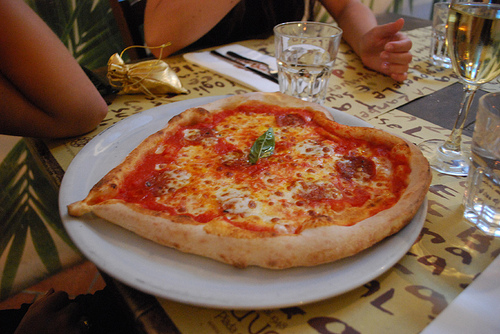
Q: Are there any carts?
A: No, there are no carts.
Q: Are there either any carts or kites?
A: No, there are no carts or kites.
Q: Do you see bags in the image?
A: Yes, there is a bag.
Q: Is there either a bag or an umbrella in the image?
A: Yes, there is a bag.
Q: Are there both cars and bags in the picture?
A: No, there is a bag but no cars.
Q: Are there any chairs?
A: No, there are no chairs.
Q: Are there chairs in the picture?
A: No, there are no chairs.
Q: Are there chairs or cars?
A: No, there are no chairs or cars.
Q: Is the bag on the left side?
A: Yes, the bag is on the left of the image.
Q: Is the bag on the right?
A: No, the bag is on the left of the image.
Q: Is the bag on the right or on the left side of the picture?
A: The bag is on the left of the image.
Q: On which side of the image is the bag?
A: The bag is on the left of the image.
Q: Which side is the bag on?
A: The bag is on the left of the image.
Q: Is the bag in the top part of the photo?
A: Yes, the bag is in the top of the image.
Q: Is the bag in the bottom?
A: No, the bag is in the top of the image.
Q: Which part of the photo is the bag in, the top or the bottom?
A: The bag is in the top of the image.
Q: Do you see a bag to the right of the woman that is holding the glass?
A: Yes, there is a bag to the right of the woman.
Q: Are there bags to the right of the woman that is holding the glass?
A: Yes, there is a bag to the right of the woman.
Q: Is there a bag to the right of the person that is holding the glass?
A: Yes, there is a bag to the right of the woman.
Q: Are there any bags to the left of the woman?
A: No, the bag is to the right of the woman.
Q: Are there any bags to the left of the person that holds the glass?
A: No, the bag is to the right of the woman.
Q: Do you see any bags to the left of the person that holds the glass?
A: No, the bag is to the right of the woman.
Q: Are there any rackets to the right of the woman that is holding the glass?
A: No, there is a bag to the right of the woman.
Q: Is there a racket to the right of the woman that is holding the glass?
A: No, there is a bag to the right of the woman.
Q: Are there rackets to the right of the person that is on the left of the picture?
A: No, there is a bag to the right of the woman.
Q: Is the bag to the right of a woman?
A: Yes, the bag is to the right of a woman.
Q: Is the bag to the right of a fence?
A: No, the bag is to the right of a woman.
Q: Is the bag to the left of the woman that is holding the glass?
A: No, the bag is to the right of the woman.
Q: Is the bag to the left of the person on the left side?
A: No, the bag is to the right of the woman.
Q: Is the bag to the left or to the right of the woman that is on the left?
A: The bag is to the right of the woman.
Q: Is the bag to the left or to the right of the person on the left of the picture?
A: The bag is to the right of the woman.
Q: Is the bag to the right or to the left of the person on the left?
A: The bag is to the right of the woman.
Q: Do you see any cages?
A: No, there are no cages.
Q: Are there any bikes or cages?
A: No, there are no cages or bikes.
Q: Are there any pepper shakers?
A: No, there are no pepper shakers.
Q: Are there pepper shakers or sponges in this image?
A: No, there are no pepper shakers or sponges.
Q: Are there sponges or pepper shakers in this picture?
A: No, there are no pepper shakers or sponges.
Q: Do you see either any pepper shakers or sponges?
A: No, there are no pepper shakers or sponges.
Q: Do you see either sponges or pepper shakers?
A: No, there are no pepper shakers or sponges.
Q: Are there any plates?
A: Yes, there is a plate.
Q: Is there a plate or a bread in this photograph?
A: Yes, there is a plate.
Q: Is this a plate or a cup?
A: This is a plate.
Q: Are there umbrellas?
A: No, there are no umbrellas.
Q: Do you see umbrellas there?
A: No, there are no umbrellas.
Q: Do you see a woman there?
A: Yes, there is a woman.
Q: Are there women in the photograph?
A: Yes, there is a woman.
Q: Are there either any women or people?
A: Yes, there is a woman.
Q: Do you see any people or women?
A: Yes, there is a woman.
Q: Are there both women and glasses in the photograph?
A: Yes, there are both a woman and glasses.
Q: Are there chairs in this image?
A: No, there are no chairs.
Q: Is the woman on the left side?
A: Yes, the woman is on the left of the image.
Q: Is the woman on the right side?
A: No, the woman is on the left of the image.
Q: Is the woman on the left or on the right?
A: The woman is on the left of the image.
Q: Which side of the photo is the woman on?
A: The woman is on the left of the image.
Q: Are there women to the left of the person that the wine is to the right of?
A: Yes, there is a woman to the left of the person.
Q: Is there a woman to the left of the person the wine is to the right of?
A: Yes, there is a woman to the left of the person.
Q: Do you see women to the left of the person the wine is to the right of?
A: Yes, there is a woman to the left of the person.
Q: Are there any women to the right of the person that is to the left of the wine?
A: No, the woman is to the left of the person.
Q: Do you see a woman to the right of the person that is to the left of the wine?
A: No, the woman is to the left of the person.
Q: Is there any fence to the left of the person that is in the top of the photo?
A: No, there is a woman to the left of the person.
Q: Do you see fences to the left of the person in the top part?
A: No, there is a woman to the left of the person.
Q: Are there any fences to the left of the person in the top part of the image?
A: No, there is a woman to the left of the person.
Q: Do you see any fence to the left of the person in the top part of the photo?
A: No, there is a woman to the left of the person.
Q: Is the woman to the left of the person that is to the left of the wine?
A: Yes, the woman is to the left of the person.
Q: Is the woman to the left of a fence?
A: No, the woman is to the left of the person.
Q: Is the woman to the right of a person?
A: No, the woman is to the left of a person.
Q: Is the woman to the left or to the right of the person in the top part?
A: The woman is to the left of the person.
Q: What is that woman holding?
A: The woman is holding the glass.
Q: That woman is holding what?
A: The woman is holding the glass.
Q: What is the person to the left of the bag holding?
A: The woman is holding the glass.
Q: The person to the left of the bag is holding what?
A: The woman is holding the glass.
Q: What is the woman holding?
A: The woman is holding the glass.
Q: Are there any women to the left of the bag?
A: Yes, there is a woman to the left of the bag.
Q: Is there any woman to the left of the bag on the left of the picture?
A: Yes, there is a woman to the left of the bag.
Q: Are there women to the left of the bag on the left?
A: Yes, there is a woman to the left of the bag.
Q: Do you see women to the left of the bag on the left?
A: Yes, there is a woman to the left of the bag.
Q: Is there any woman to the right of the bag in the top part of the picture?
A: No, the woman is to the left of the bag.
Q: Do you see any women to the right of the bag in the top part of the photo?
A: No, the woman is to the left of the bag.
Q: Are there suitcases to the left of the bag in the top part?
A: No, there is a woman to the left of the bag.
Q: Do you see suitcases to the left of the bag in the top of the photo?
A: No, there is a woman to the left of the bag.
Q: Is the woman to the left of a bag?
A: Yes, the woman is to the left of a bag.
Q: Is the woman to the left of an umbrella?
A: No, the woman is to the left of a bag.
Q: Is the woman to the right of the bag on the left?
A: No, the woman is to the left of the bag.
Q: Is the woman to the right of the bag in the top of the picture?
A: No, the woman is to the left of the bag.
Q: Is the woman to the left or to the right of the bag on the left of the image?
A: The woman is to the left of the bag.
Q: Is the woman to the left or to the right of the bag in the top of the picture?
A: The woman is to the left of the bag.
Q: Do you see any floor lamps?
A: No, there are no floor lamps.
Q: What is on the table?
A: The glass is on the table.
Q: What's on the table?
A: The glass is on the table.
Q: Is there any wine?
A: Yes, there is wine.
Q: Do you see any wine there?
A: Yes, there is wine.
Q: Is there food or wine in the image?
A: Yes, there is wine.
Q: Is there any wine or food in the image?
A: Yes, there is wine.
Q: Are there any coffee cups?
A: No, there are no coffee cups.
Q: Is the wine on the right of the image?
A: Yes, the wine is on the right of the image.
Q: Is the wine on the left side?
A: No, the wine is on the right of the image.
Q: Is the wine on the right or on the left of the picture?
A: The wine is on the right of the image.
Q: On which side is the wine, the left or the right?
A: The wine is on the right of the image.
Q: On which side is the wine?
A: The wine is on the right of the image.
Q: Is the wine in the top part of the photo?
A: Yes, the wine is in the top of the image.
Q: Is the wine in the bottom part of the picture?
A: No, the wine is in the top of the image.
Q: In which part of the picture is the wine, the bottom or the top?
A: The wine is in the top of the image.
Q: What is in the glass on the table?
A: The wine is in the glass.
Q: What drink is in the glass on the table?
A: The drink is wine.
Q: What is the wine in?
A: The wine is in the glass.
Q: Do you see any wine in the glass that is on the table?
A: Yes, there is wine in the glass.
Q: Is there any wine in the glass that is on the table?
A: Yes, there is wine in the glass.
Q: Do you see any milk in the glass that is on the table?
A: No, there is wine in the glass.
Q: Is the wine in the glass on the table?
A: Yes, the wine is in the glass.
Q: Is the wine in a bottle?
A: No, the wine is in the glass.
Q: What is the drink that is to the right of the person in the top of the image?
A: The drink is wine.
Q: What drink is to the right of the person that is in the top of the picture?
A: The drink is wine.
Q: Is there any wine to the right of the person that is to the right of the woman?
A: Yes, there is wine to the right of the person.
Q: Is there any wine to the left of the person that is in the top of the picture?
A: No, the wine is to the right of the person.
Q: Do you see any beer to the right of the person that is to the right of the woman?
A: No, there is wine to the right of the person.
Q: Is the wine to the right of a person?
A: Yes, the wine is to the right of a person.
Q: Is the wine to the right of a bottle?
A: No, the wine is to the right of a person.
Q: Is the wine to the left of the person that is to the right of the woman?
A: No, the wine is to the right of the person.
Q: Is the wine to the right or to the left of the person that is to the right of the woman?
A: The wine is to the right of the person.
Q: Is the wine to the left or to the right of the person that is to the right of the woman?
A: The wine is to the right of the person.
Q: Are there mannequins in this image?
A: No, there are no mannequins.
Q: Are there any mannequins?
A: No, there are no mannequins.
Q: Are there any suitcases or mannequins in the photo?
A: No, there are no mannequins or suitcases.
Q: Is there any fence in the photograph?
A: No, there are no fences.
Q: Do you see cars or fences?
A: No, there are no fences or cars.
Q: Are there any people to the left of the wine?
A: Yes, there is a person to the left of the wine.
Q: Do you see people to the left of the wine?
A: Yes, there is a person to the left of the wine.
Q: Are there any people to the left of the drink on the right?
A: Yes, there is a person to the left of the wine.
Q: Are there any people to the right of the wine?
A: No, the person is to the left of the wine.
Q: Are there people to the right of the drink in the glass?
A: No, the person is to the left of the wine.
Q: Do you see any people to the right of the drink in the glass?
A: No, the person is to the left of the wine.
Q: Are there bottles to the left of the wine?
A: No, there is a person to the left of the wine.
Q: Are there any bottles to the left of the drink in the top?
A: No, there is a person to the left of the wine.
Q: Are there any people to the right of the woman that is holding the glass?
A: Yes, there is a person to the right of the woman.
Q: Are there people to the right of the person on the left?
A: Yes, there is a person to the right of the woman.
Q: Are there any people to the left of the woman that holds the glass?
A: No, the person is to the right of the woman.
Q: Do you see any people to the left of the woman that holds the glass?
A: No, the person is to the right of the woman.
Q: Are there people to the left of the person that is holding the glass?
A: No, the person is to the right of the woman.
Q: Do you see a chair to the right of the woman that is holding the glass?
A: No, there is a person to the right of the woman.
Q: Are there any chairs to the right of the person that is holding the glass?
A: No, there is a person to the right of the woman.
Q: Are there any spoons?
A: No, there are no spoons.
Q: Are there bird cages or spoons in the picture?
A: No, there are no spoons or bird cages.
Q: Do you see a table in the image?
A: Yes, there is a table.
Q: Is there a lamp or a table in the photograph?
A: Yes, there is a table.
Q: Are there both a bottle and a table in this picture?
A: No, there is a table but no bottles.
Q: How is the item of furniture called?
A: The piece of furniture is a table.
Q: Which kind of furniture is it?
A: The piece of furniture is a table.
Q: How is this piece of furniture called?
A: That is a table.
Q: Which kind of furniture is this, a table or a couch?
A: That is a table.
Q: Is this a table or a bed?
A: This is a table.